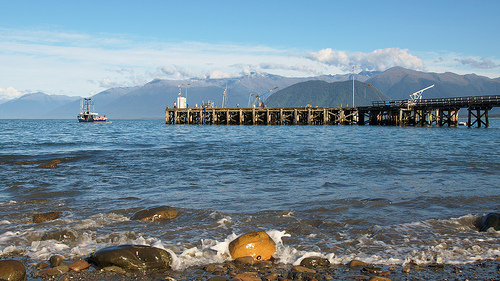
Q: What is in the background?
A: Mountains.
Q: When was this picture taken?
A: Daytime.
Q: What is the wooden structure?
A: Pier.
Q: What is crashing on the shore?
A: Waves.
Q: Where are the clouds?
A: In the sky.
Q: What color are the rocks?
A: Brown.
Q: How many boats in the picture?
A: One.